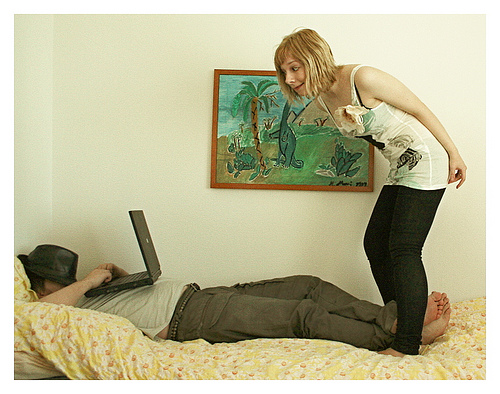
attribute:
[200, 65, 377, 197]
picture frame — large, brown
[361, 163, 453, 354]
pants — black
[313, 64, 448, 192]
top — white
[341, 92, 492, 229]
tank top — white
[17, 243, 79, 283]
hat — leather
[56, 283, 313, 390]
sheets — yellow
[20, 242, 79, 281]
hat — black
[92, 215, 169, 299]
laptop — black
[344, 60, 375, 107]
strap — black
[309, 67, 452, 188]
shirt — white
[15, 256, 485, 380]
bedspread — yellow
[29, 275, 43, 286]
hair — dark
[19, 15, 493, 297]
wall — white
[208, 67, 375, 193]
painting — framed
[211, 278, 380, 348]
pants — dark tan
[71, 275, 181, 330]
shirt — white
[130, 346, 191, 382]
flowers — orange, white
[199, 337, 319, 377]
flowers — white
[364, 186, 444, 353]
jeans — skin tight, black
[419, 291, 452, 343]
feet — bare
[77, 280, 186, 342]
shirt — white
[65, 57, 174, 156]
wall — white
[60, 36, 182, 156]
wall — white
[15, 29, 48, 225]
wall — white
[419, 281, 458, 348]
feet — bare